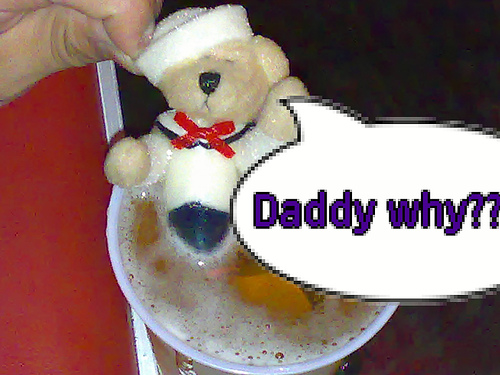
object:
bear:
[109, 4, 316, 246]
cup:
[122, 115, 379, 371]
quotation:
[250, 188, 498, 234]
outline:
[239, 108, 500, 300]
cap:
[134, 6, 254, 63]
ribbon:
[174, 113, 236, 159]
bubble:
[242, 339, 295, 362]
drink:
[102, 100, 405, 374]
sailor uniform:
[140, 109, 259, 261]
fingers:
[92, 2, 157, 53]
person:
[1, 2, 163, 120]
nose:
[196, 72, 222, 94]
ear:
[252, 42, 288, 85]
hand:
[258, 80, 314, 134]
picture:
[3, 2, 497, 374]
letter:
[249, 190, 495, 231]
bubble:
[240, 126, 496, 296]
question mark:
[465, 187, 490, 237]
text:
[252, 189, 499, 242]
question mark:
[480, 190, 499, 230]